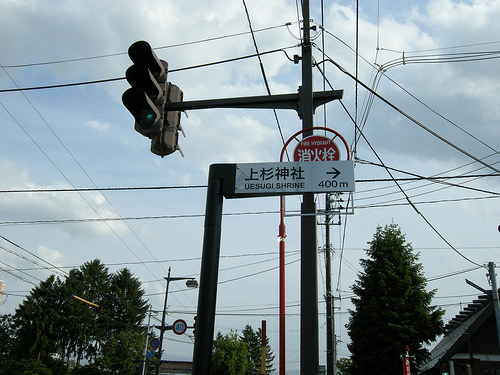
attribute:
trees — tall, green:
[344, 224, 451, 369]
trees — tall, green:
[216, 321, 266, 372]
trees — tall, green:
[1, 257, 158, 371]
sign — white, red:
[292, 135, 340, 163]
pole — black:
[161, 7, 342, 373]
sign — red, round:
[290, 134, 340, 164]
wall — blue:
[255, 67, 356, 103]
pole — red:
[274, 190, 293, 375]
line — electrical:
[12, 73, 126, 89]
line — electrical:
[155, 31, 250, 48]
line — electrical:
[257, 55, 269, 92]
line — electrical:
[55, 184, 169, 191]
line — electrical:
[386, 168, 425, 219]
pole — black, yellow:
[259, 316, 272, 373]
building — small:
[25, 28, 82, 58]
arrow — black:
[324, 165, 339, 181]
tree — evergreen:
[336, 188, 455, 366]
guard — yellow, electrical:
[62, 286, 111, 315]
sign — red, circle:
[295, 147, 334, 161]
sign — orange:
[288, 137, 341, 162]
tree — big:
[337, 215, 447, 372]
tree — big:
[210, 320, 275, 370]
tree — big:
[92, 322, 157, 372]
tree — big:
[94, 264, 153, 349]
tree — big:
[0, 269, 78, 366]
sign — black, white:
[218, 152, 379, 209]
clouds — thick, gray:
[5, 4, 115, 203]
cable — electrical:
[377, 40, 498, 53]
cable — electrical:
[314, 42, 497, 172]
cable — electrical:
[2, 41, 303, 94]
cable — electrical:
[145, 261, 498, 314]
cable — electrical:
[0, 64, 197, 345]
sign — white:
[232, 159, 357, 195]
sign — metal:
[172, 319, 186, 337]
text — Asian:
[248, 166, 300, 180]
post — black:
[188, 163, 226, 373]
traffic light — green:
[125, 35, 172, 141]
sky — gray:
[5, 1, 499, 372]